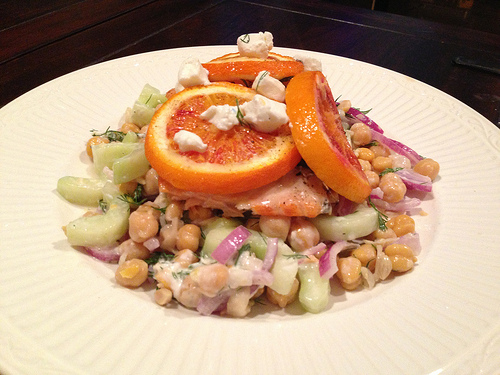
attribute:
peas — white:
[332, 244, 420, 279]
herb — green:
[117, 184, 150, 207]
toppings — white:
[140, 32, 372, 228]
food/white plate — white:
[5, 45, 485, 362]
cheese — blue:
[141, 84, 359, 159]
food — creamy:
[99, 84, 429, 241]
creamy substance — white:
[156, 266, 180, 284]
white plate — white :
[3, 30, 495, 372]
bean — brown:
[124, 207, 156, 239]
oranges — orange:
[143, 48, 372, 203]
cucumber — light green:
[58, 128, 143, 238]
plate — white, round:
[2, 31, 499, 373]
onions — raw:
[213, 224, 252, 265]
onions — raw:
[320, 241, 360, 282]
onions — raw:
[396, 169, 432, 192]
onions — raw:
[265, 239, 277, 271]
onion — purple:
[381, 134, 423, 164]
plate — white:
[15, 22, 490, 361]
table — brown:
[2, 2, 497, 142]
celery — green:
[67, 197, 127, 249]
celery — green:
[89, 142, 146, 178]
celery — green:
[56, 175, 111, 202]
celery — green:
[315, 203, 375, 237]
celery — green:
[276, 258, 326, 308]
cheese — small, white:
[234, 32, 271, 50]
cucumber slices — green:
[64, 176, 114, 200]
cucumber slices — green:
[75, 185, 128, 245]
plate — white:
[434, 263, 494, 350]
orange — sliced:
[138, 82, 300, 192]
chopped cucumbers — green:
[58, 139, 147, 246]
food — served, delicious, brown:
[52, 25, 443, 324]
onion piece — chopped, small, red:
[216, 225, 248, 267]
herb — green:
[224, 93, 252, 131]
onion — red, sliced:
[355, 109, 422, 166]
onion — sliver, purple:
[210, 222, 250, 272]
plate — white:
[441, 232, 498, 369]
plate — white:
[20, 240, 129, 350]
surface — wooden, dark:
[330, 13, 493, 51]